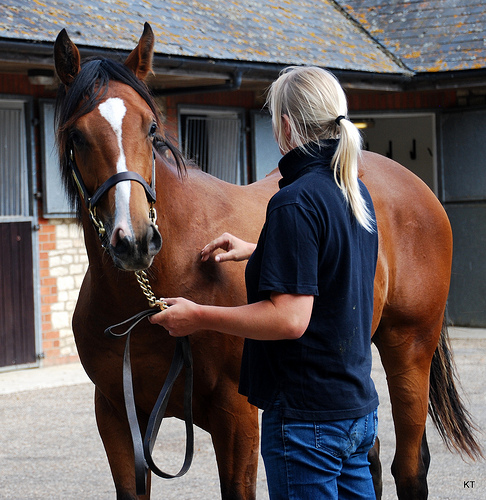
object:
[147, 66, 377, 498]
lady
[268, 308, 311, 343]
elbow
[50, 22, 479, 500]
horse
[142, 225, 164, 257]
nostril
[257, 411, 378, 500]
jeans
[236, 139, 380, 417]
shirt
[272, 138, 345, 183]
collar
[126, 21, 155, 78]
ear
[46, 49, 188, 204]
mane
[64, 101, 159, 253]
bridle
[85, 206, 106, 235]
metal accents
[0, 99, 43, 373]
stable door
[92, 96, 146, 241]
stripe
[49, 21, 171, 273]
horse's face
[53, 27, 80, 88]
pointed ear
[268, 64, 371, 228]
hair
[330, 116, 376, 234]
ponytail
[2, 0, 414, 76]
roof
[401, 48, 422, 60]
spot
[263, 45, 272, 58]
spot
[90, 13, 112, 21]
spot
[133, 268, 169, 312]
chain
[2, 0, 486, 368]
building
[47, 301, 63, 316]
bricks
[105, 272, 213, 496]
leash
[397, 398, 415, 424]
veins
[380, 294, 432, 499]
leg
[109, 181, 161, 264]
nose